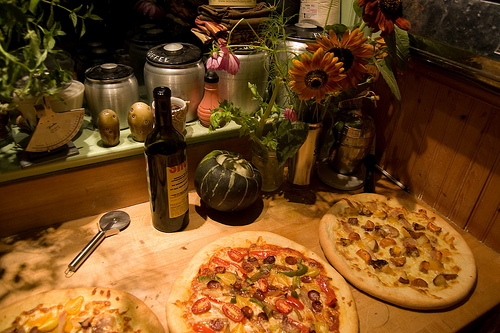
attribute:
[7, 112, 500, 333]
counter — brown, wooden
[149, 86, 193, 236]
bottle — pink, green, dark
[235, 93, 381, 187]
vase — glass, silver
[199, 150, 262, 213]
pumpkin — green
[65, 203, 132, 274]
spoon — silver, metal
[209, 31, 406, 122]
flower — pink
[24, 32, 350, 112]
metal canister — silver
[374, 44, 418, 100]
leaf — green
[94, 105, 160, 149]
salt shakers — ceramic